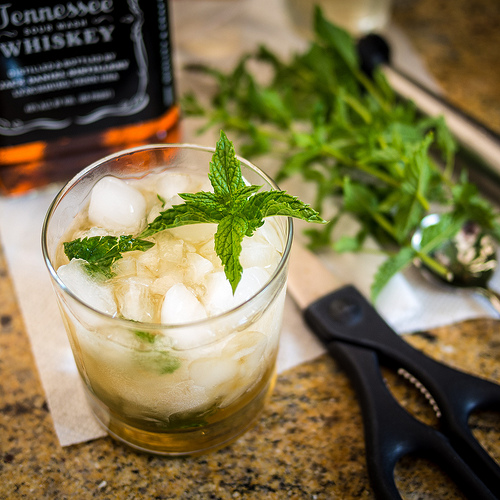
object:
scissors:
[277, 236, 497, 497]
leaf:
[207, 126, 242, 198]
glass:
[40, 132, 295, 458]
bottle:
[0, 1, 182, 195]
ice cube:
[88, 174, 144, 230]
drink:
[42, 142, 295, 455]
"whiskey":
[3, 27, 118, 56]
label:
[0, 2, 178, 149]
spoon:
[320, 0, 498, 200]